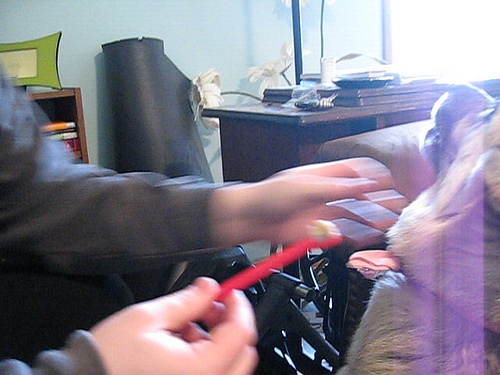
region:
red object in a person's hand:
[185, 217, 350, 304]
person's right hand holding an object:
[63, 249, 265, 370]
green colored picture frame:
[0, 30, 74, 96]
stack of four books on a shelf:
[31, 109, 85, 161]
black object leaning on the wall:
[93, 27, 214, 224]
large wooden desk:
[193, 57, 495, 178]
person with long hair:
[413, 77, 491, 182]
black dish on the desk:
[332, 70, 394, 90]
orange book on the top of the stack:
[30, 116, 75, 132]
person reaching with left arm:
[2, 72, 399, 271]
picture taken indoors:
[34, 64, 422, 374]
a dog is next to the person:
[310, 97, 497, 362]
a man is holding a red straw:
[143, 160, 370, 355]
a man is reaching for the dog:
[241, 85, 469, 276]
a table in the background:
[222, 41, 430, 121]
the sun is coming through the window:
[370, 30, 490, 131]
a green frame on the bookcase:
[22, 9, 100, 152]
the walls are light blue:
[71, 31, 266, 43]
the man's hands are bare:
[191, 154, 430, 365]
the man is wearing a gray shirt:
[51, 133, 283, 350]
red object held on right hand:
[215, 247, 312, 300]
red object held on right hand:
[209, 237, 346, 317]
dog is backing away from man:
[374, 102, 488, 200]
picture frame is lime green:
[13, 33, 75, 110]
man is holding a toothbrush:
[199, 226, 406, 287]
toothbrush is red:
[117, 227, 407, 293]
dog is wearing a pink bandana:
[344, 244, 498, 291]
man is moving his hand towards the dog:
[233, 152, 484, 244]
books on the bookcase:
[25, 114, 123, 191]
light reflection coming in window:
[369, 9, 498, 83]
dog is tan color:
[348, 171, 497, 373]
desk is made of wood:
[223, 87, 466, 155]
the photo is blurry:
[80, 69, 492, 363]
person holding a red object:
[167, 187, 357, 341]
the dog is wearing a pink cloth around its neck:
[320, 219, 481, 335]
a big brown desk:
[195, 60, 410, 178]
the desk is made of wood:
[152, 69, 420, 183]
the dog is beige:
[336, 73, 498, 366]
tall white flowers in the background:
[156, 42, 298, 147]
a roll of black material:
[80, 7, 209, 167]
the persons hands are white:
[87, 137, 384, 362]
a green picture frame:
[0, 22, 81, 102]